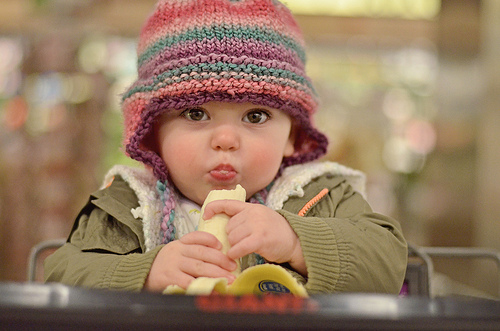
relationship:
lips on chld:
[209, 160, 236, 179] [30, 15, 410, 329]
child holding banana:
[33, 0, 435, 293] [172, 179, 267, 297]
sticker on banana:
[252, 274, 295, 297] [161, 182, 315, 311]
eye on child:
[184, 103, 213, 126] [33, 0, 435, 293]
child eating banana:
[33, 0, 435, 293] [161, 182, 315, 311]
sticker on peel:
[256, 278, 289, 294] [220, 266, 317, 291]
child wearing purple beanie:
[33, 0, 435, 293] [123, 0, 327, 179]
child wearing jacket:
[33, 0, 435, 293] [44, 169, 409, 294]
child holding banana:
[107, 4, 341, 276] [160, 186, 316, 295]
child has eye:
[33, 0, 435, 293] [176, 106, 212, 123]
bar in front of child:
[0, 276, 498, 328] [33, 0, 435, 293]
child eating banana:
[33, 0, 435, 293] [150, 178, 305, 303]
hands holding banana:
[157, 197, 298, 287] [197, 180, 249, 272]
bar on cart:
[414, 229, 472, 261] [0, 233, 485, 329]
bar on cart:
[0, 276, 498, 328] [0, 233, 485, 329]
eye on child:
[237, 107, 269, 121] [33, 0, 435, 293]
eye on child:
[176, 106, 212, 123] [33, 0, 435, 293]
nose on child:
[210, 114, 240, 151] [33, 0, 435, 293]